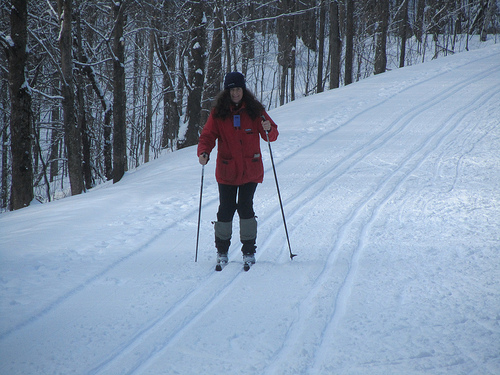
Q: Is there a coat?
A: Yes, there is a coat.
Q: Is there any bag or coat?
A: Yes, there is a coat.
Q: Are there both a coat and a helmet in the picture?
A: No, there is a coat but no helmets.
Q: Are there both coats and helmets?
A: No, there is a coat but no helmets.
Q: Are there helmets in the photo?
A: No, there are no helmets.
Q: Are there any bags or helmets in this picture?
A: No, there are no helmets or bags.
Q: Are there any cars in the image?
A: No, there are no cars.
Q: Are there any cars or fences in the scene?
A: No, there are no cars or fences.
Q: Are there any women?
A: Yes, there is a woman.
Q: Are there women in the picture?
A: Yes, there is a woman.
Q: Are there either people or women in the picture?
A: Yes, there is a woman.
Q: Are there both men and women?
A: No, there is a woman but no men.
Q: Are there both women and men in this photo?
A: No, there is a woman but no men.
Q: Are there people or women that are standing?
A: Yes, the woman is standing.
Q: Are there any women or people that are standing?
A: Yes, the woman is standing.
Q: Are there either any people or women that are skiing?
A: Yes, the woman is skiing.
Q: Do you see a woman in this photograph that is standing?
A: Yes, there is a woman that is standing.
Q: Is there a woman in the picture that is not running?
A: Yes, there is a woman that is standing.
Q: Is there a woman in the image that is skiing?
A: Yes, there is a woman that is skiing.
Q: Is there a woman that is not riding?
A: Yes, there is a woman that is skiing.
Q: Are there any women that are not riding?
A: Yes, there is a woman that is skiing.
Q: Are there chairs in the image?
A: No, there are no chairs.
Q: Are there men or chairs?
A: No, there are no chairs or men.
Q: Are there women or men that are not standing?
A: No, there is a woman but she is standing.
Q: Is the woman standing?
A: Yes, the woman is standing.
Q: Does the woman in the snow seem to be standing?
A: Yes, the woman is standing.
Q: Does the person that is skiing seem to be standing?
A: Yes, the woman is standing.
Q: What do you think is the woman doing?
A: The woman is standing.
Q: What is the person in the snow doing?
A: The woman is standing.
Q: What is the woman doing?
A: The woman is standing.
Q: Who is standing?
A: The woman is standing.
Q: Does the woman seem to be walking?
A: No, the woman is standing.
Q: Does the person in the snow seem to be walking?
A: No, the woman is standing.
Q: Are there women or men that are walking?
A: No, there is a woman but she is standing.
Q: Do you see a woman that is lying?
A: No, there is a woman but she is standing.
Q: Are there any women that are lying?
A: No, there is a woman but she is standing.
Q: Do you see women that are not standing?
A: No, there is a woman but she is standing.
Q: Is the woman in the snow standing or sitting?
A: The woman is standing.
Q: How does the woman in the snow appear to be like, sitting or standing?
A: The woman is standing.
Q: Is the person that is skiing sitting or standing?
A: The woman is standing.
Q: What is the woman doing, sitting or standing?
A: The woman is standing.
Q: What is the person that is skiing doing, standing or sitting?
A: The woman is standing.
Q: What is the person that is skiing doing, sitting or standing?
A: The woman is standing.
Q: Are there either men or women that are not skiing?
A: No, there is a woman but she is skiing.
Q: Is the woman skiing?
A: Yes, the woman is skiing.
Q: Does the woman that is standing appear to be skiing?
A: Yes, the woman is skiing.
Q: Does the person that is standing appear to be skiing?
A: Yes, the woman is skiing.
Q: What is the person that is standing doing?
A: The woman is skiing.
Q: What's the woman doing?
A: The woman is skiing.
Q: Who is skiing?
A: The woman is skiing.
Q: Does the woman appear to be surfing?
A: No, the woman is skiing.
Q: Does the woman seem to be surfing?
A: No, the woman is skiing.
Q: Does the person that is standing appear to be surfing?
A: No, the woman is skiing.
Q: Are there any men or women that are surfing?
A: No, there is a woman but she is skiing.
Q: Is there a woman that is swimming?
A: No, there is a woman but she is skiing.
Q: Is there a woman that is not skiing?
A: No, there is a woman but she is skiing.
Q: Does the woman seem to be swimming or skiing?
A: The woman is skiing.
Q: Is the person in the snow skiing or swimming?
A: The woman is skiing.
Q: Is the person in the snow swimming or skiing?
A: The woman is skiing.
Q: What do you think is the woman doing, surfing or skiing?
A: The woman is skiing.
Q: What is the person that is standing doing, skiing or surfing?
A: The woman is skiing.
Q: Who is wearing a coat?
A: The woman is wearing a coat.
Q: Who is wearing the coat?
A: The woman is wearing a coat.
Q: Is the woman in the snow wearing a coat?
A: Yes, the woman is wearing a coat.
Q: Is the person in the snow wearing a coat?
A: Yes, the woman is wearing a coat.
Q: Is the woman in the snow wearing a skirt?
A: No, the woman is wearing a coat.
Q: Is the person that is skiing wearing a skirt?
A: No, the woman is wearing a coat.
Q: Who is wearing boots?
A: The woman is wearing boots.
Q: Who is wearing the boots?
A: The woman is wearing boots.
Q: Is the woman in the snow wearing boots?
A: Yes, the woman is wearing boots.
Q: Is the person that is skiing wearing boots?
A: Yes, the woman is wearing boots.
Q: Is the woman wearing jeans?
A: No, the woman is wearing boots.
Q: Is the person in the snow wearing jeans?
A: No, the woman is wearing boots.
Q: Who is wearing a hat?
A: The woman is wearing a hat.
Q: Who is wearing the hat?
A: The woman is wearing a hat.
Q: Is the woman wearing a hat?
A: Yes, the woman is wearing a hat.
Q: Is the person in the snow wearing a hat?
A: Yes, the woman is wearing a hat.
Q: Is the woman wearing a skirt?
A: No, the woman is wearing a hat.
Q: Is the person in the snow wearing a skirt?
A: No, the woman is wearing a hat.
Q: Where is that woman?
A: The woman is in the snow.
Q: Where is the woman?
A: The woman is in the snow.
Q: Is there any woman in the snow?
A: Yes, there is a woman in the snow.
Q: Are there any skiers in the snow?
A: No, there is a woman in the snow.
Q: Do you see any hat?
A: Yes, there is a hat.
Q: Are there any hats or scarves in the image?
A: Yes, there is a hat.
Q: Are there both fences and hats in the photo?
A: No, there is a hat but no fences.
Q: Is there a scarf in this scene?
A: No, there are no scarves.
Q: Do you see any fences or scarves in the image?
A: No, there are no scarves or fences.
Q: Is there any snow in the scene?
A: Yes, there is snow.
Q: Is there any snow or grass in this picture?
A: Yes, there is snow.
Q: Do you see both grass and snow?
A: No, there is snow but no grass.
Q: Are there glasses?
A: No, there are no glasses.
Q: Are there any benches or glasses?
A: No, there are no glasses or benches.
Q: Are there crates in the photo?
A: No, there are no crates.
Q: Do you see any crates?
A: No, there are no crates.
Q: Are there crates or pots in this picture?
A: No, there are no crates or pots.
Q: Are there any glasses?
A: No, there are no glasses.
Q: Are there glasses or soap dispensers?
A: No, there are no glasses or soap dispensers.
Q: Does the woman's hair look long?
A: Yes, the hair is long.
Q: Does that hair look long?
A: Yes, the hair is long.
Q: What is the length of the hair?
A: The hair is long.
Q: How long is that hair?
A: The hair is long.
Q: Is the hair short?
A: No, the hair is long.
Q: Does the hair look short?
A: No, the hair is long.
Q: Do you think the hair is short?
A: No, the hair is long.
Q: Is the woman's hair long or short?
A: The hair is long.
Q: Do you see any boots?
A: Yes, there are boots.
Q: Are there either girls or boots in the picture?
A: Yes, there are boots.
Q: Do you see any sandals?
A: No, there are no sandals.